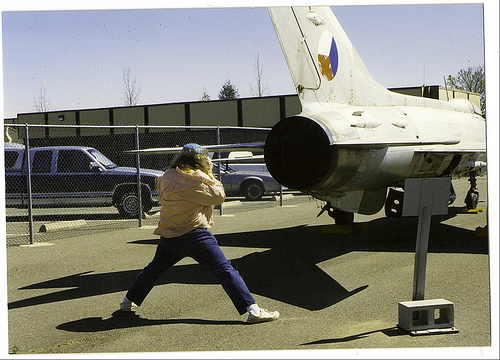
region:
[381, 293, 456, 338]
a concrete cinder block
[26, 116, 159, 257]
a chain link fence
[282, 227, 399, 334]
a shadow on the ground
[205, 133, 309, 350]
a person wearing white shoes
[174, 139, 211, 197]
a person wearing a hat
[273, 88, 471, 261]
a rocket parked next to a fence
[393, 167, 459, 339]
a sign next to a block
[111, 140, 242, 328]
a person with their legs spread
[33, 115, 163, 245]
a truck parked next to a fence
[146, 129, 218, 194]
a person with long hair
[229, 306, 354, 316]
This is a picture of a shoe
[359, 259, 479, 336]
This is a block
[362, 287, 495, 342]
The block is concrete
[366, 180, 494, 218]
This is a sign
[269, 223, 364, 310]
This is a shadow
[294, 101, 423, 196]
This is a plane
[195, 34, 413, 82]
This is a wing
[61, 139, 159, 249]
This is a fence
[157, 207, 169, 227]
The coat is yellow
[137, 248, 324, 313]
The pants are jeans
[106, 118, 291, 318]
person behind a plane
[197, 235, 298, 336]
leg of the person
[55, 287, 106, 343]
shadow on the ground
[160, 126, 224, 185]
hat on person's head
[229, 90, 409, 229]
back of the plane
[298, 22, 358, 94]
symbol on back of plane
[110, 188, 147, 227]
tire on the car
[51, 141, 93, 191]
window on side of car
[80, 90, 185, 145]
building in the background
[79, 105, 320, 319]
person with back towards camera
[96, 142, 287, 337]
a person with outstretched legs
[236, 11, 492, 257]
a small white plane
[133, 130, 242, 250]
person is blonde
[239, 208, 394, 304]
shadow cast on the ground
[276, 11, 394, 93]
vertical stabilizer of a plane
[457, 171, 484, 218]
the front wheel of a plane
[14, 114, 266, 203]
car in a parking lot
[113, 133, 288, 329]
man wears blue pants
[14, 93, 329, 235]
a fence on side the plane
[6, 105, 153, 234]
fence is metal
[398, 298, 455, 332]
Grey cement brick block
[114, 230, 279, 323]
Individual with legs spread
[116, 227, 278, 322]
Individual with blue pants and sneakers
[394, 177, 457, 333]
Grey sign supported by brick block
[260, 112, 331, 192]
Jet airplane rear engine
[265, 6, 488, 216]
Grey single engine jet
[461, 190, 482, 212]
Down airplane wheel surrounded by yellow chocks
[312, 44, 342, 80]
Emblem on plane's tail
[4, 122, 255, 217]
Grey chain link fence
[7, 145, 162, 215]
Pickup truck with camper shell